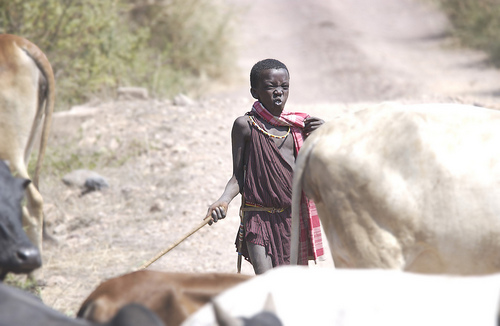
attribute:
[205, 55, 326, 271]
child — herding, making face, walking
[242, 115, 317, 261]
clothes — dark, purple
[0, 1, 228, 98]
grass — green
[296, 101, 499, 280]
animal — white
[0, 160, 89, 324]
cow — black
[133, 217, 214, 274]
stick — brown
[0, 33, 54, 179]
cow — beige, tan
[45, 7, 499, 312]
road — rock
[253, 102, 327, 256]
scarf — pink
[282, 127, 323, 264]
tail — hanging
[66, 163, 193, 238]
rocks — here, gray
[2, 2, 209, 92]
bush — green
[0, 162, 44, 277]
face — black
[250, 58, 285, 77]
hair — black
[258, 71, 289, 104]
face — scrunched up